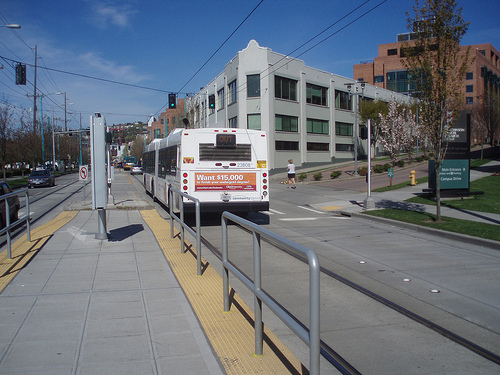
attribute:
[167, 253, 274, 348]
paint — yellow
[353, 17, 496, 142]
brick building — large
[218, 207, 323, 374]
railing — silver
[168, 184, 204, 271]
railing — silver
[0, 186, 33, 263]
railing — silver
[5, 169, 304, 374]
ground — yellow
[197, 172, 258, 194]
ad — red, orange, white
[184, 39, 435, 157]
building — large, white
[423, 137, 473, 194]
sign — green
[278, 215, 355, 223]
line — white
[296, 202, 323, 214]
line — white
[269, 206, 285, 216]
line — white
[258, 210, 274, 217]
line — white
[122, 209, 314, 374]
curb — yellow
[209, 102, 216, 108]
light — green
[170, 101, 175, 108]
light — green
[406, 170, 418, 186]
fire hydrant — yellow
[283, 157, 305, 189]
shirt — white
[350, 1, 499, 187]
building — brown, brick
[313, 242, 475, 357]
track — steel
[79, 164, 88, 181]
sign — red, white, and black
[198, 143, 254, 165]
vents — black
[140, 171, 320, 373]
railing — silver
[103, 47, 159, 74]
sky — blue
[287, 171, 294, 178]
shorts — black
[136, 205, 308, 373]
edge — yellow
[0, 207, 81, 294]
edge — yellow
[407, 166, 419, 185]
fire hydrant — yellow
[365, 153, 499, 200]
sidewalk — sloped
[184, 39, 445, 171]
building — white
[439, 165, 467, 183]
letters — white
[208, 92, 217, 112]
traffic light — lit up, green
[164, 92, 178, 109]
traffic light — lit up, green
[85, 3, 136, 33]
cloud — white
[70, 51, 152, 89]
cloud — white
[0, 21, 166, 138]
cloud — white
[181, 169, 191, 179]
light — rear, red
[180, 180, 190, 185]
light — rear, red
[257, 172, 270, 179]
light — rear, red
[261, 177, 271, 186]
light — rear, red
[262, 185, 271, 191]
light — rear, red